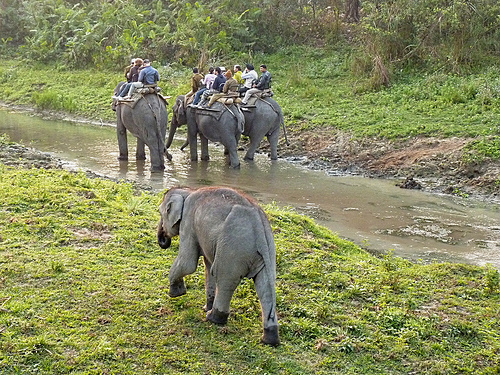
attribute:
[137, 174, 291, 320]
elephant — by, walking, baby, grey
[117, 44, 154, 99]
man — wearing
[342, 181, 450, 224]
water — murky, dirty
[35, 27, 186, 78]
bush — dense, green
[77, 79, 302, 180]
elephants — three, ridden, riding, four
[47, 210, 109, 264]
grass — patchy, green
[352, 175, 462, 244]
rocks — patch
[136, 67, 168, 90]
shirt — denim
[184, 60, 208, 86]
hair — brown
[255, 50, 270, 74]
cap — brown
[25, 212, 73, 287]
plants — tropical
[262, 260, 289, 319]
tail — long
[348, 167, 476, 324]
muddy — small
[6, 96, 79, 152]
shore — grassy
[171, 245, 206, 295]
leg — raised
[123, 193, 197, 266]
ear — folded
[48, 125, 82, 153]
they — water